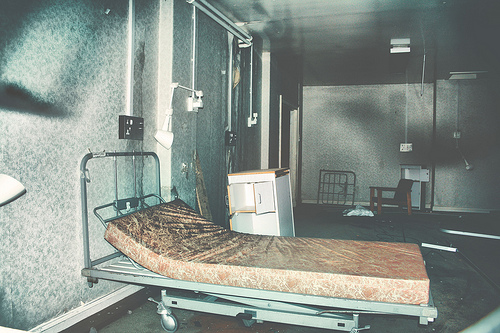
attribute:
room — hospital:
[64, 16, 455, 282]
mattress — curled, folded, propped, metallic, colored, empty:
[49, 177, 370, 289]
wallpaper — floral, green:
[37, 37, 101, 82]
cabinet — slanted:
[240, 184, 295, 233]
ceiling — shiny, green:
[322, 12, 361, 29]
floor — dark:
[314, 217, 334, 227]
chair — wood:
[369, 185, 410, 220]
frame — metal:
[67, 138, 150, 190]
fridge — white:
[277, 181, 291, 194]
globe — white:
[174, 91, 196, 112]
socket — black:
[99, 115, 159, 145]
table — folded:
[317, 169, 350, 201]